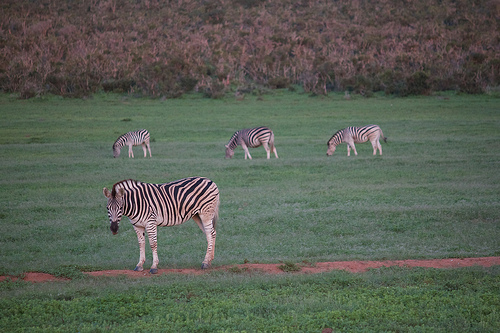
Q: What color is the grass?
A: Green.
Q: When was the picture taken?
A: Daytime.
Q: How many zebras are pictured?
A: 4.